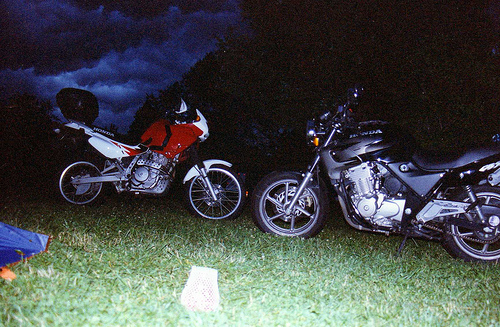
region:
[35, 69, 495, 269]
There are two motorcycles.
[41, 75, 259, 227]
One motorcycle is smaller than the other.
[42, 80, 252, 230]
One motorcycle is red.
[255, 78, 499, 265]
One motorcycle is black.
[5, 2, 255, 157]
The sky is full of clouds.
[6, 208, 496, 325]
There is grass on the ground.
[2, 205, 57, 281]
The corner of a tent is visible.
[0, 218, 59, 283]
The tent is blue.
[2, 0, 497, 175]
The photo is a nighttime scene.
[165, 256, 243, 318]
There is a white object on the grass.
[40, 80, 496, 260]
Two parked Motorcycles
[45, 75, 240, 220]
White and red Motorcycle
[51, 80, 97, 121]
Black toolbox of motorcycle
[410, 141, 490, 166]
Single seat of motorcycle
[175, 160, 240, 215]
Front tire of motorcycle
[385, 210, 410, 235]
Pedal in the left side of motorcycle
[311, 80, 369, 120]
Grey grip of motorcycle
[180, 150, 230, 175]
Front fender over the wheel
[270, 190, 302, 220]
Rotor of motorcycle wheel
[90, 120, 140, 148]
Passenger seat of red and white motorcycle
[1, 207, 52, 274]
A piece of a blue tarp on grass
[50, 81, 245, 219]
A red and white motorcycle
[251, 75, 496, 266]
A black motorcycle in grass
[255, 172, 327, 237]
Front tire on black motorcycle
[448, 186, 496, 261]
Back tire on black motorcycle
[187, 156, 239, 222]
Front tire on red and white motorcycle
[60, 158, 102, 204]
Back tire on red and white motorcycle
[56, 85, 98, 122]
Luggage compartment on red and white motorcycle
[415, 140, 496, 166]
Seat on black motorcycle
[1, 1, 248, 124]
White rushing water at night near motorcycles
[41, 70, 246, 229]
Red and white motorcycle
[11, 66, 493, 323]
Tan motorcycle on grass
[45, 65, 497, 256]
Two parked motorcycles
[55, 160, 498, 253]
Wheeles of motorcycle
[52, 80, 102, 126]
Black box tools of red and white motorcycle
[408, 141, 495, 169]
Single sit motorcycle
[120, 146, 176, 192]
Engine of red and white motorcycle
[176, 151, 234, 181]
Front fender of motorcycle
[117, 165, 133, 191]
Pedal of red and white motorcycle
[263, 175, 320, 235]
Aluminium rim of motorcycle